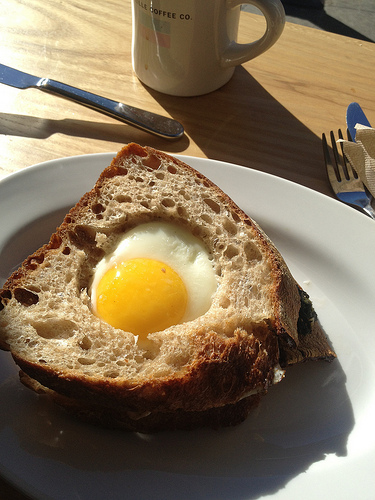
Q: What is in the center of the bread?
A: An egg.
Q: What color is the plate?
A: White.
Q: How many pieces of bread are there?
A: 2.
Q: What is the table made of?
A: Wood.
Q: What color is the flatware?
A: Silver.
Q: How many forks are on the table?
A: 1.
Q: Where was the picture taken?
A: Cooked in the bread.